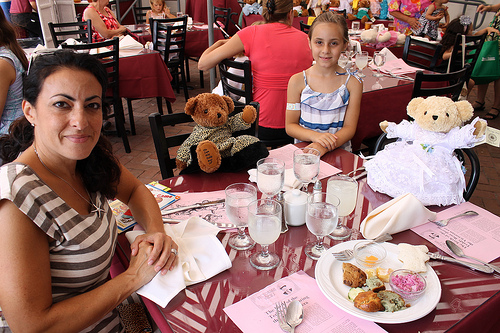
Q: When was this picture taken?
A: Daytime.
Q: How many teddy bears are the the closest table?
A: 2.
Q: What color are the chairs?
A: Black.